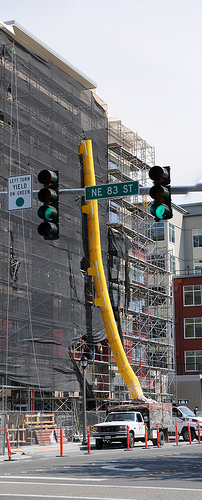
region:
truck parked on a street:
[89, 396, 174, 450]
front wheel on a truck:
[125, 431, 134, 448]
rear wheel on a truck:
[151, 429, 166, 446]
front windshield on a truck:
[102, 411, 136, 422]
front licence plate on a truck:
[103, 434, 111, 440]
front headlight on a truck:
[117, 423, 126, 431]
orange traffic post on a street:
[82, 422, 93, 454]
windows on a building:
[180, 282, 200, 309]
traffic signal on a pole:
[146, 162, 176, 224]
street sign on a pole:
[81, 178, 141, 201]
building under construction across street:
[5, 129, 169, 427]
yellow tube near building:
[77, 193, 150, 387]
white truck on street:
[92, 386, 175, 444]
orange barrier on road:
[2, 422, 19, 457]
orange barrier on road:
[55, 423, 69, 455]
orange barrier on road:
[81, 422, 98, 457]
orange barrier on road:
[122, 424, 138, 455]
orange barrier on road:
[139, 425, 149, 446]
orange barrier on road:
[155, 420, 163, 447]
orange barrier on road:
[170, 421, 183, 445]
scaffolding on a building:
[110, 132, 141, 176]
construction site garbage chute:
[68, 123, 150, 408]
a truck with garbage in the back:
[92, 391, 173, 443]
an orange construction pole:
[58, 424, 66, 458]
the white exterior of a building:
[178, 218, 188, 247]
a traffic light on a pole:
[36, 166, 61, 237]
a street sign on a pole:
[75, 177, 145, 200]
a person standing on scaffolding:
[96, 338, 107, 363]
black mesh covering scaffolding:
[25, 73, 65, 148]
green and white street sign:
[79, 179, 144, 202]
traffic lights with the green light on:
[139, 151, 177, 223]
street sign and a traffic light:
[75, 156, 182, 225]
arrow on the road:
[99, 453, 154, 483]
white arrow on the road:
[98, 449, 147, 485]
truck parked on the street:
[89, 390, 179, 449]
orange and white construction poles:
[81, 419, 96, 458]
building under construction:
[9, 19, 147, 221]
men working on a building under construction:
[86, 336, 109, 366]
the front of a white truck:
[175, 393, 201, 440]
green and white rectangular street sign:
[83, 179, 139, 201]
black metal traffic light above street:
[148, 163, 173, 222]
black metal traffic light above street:
[36, 168, 60, 241]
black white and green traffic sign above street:
[6, 173, 33, 211]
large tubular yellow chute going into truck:
[77, 137, 144, 401]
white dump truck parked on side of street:
[90, 399, 174, 450]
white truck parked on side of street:
[119, 398, 200, 442]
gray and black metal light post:
[78, 355, 88, 445]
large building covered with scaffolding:
[0, 17, 176, 454]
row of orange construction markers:
[2, 419, 200, 461]